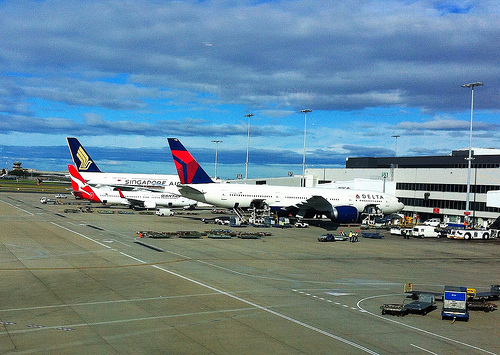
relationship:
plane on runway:
[167, 137, 405, 223] [0, 190, 499, 354]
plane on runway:
[67, 164, 212, 209] [0, 190, 499, 354]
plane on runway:
[66, 135, 225, 194] [0, 190, 499, 354]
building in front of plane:
[229, 148, 499, 229] [167, 137, 405, 223]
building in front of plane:
[229, 148, 499, 229] [67, 164, 212, 209]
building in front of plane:
[229, 148, 499, 229] [66, 135, 225, 194]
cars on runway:
[411, 217, 499, 240] [0, 190, 499, 354]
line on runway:
[2, 314, 259, 336] [0, 190, 499, 354]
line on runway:
[1, 291, 221, 312] [0, 190, 499, 354]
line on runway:
[1, 199, 379, 354] [0, 190, 499, 354]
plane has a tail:
[167, 137, 405, 223] [166, 136, 213, 183]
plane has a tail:
[67, 164, 212, 209] [68, 165, 88, 187]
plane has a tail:
[66, 135, 225, 194] [65, 135, 100, 171]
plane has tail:
[167, 137, 405, 223] [166, 136, 213, 183]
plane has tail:
[67, 164, 212, 209] [68, 165, 88, 187]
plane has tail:
[66, 135, 225, 194] [65, 135, 100, 171]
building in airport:
[229, 148, 499, 229] [0, 82, 499, 354]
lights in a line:
[211, 82, 499, 213] [211, 80, 482, 213]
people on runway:
[347, 230, 360, 242] [0, 190, 499, 354]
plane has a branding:
[167, 137, 405, 223] [360, 191, 385, 199]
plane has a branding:
[67, 164, 212, 209] [159, 194, 182, 199]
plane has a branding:
[66, 135, 225, 194] [125, 180, 182, 187]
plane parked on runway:
[167, 137, 405, 223] [0, 190, 499, 354]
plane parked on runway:
[67, 164, 212, 209] [0, 190, 499, 354]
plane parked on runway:
[66, 135, 225, 194] [0, 190, 499, 354]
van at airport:
[412, 225, 440, 238] [0, 82, 499, 354]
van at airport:
[422, 215, 439, 226] [0, 82, 499, 354]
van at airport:
[156, 207, 174, 215] [0, 82, 499, 354]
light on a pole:
[461, 81, 482, 89] [465, 85, 476, 210]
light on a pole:
[299, 109, 307, 113] [301, 115, 309, 174]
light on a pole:
[244, 111, 252, 116] [245, 117, 251, 180]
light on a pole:
[211, 139, 223, 144] [215, 145, 219, 178]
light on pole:
[461, 81, 482, 89] [465, 85, 476, 210]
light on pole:
[299, 109, 307, 113] [301, 115, 309, 174]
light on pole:
[244, 111, 252, 116] [245, 117, 251, 180]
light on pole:
[211, 139, 223, 144] [215, 145, 219, 178]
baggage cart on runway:
[440, 283, 498, 324] [0, 190, 499, 354]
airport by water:
[0, 82, 499, 354] [0, 157, 346, 178]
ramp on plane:
[234, 209, 248, 226] [167, 137, 405, 223]